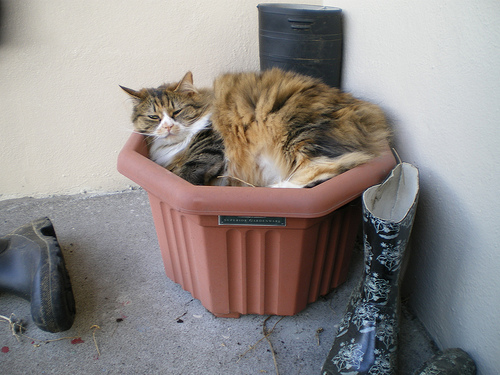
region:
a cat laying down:
[116, 66, 397, 191]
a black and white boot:
[319, 164, 486, 373]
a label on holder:
[214, 217, 292, 230]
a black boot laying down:
[1, 212, 81, 334]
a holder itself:
[117, 134, 399, 319]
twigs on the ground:
[2, 300, 338, 374]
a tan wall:
[4, 0, 498, 369]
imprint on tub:
[148, 207, 357, 322]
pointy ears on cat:
[115, 69, 200, 97]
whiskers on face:
[128, 117, 210, 137]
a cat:
[121, 87, 236, 152]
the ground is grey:
[139, 319, 186, 361]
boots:
[331, 298, 397, 372]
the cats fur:
[228, 77, 313, 129]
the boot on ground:
[3, 224, 83, 331]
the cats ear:
[171, 76, 198, 91]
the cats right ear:
[116, 82, 144, 102]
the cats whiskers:
[125, 127, 148, 138]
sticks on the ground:
[248, 325, 286, 365]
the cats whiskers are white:
[183, 123, 205, 132]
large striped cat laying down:
[119, 69, 362, 171]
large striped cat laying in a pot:
[137, 78, 382, 258]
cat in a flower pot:
[134, 74, 354, 308]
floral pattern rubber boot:
[343, 175, 392, 374]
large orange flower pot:
[123, 140, 371, 299]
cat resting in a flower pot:
[118, 44, 374, 234]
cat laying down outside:
[127, 59, 347, 255]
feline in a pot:
[124, 75, 379, 260]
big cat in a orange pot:
[112, 54, 366, 230]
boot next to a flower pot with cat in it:
[358, 180, 403, 372]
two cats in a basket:
[98, 63, 418, 323]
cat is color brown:
[208, 65, 393, 191]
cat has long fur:
[209, 65, 401, 192]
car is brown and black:
[111, 62, 226, 187]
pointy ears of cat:
[110, 65, 197, 98]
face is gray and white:
[139, 84, 202, 139]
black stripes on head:
[139, 85, 184, 112]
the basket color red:
[110, 152, 391, 322]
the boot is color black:
[5, 212, 80, 333]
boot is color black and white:
[309, 159, 431, 374]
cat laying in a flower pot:
[97, 46, 397, 351]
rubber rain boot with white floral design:
[329, 150, 439, 372]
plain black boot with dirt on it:
[6, 196, 90, 351]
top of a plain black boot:
[231, 0, 366, 76]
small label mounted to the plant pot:
[211, 211, 296, 223]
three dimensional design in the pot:
[212, 226, 302, 326]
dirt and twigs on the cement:
[159, 312, 294, 371]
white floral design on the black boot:
[353, 297, 389, 334]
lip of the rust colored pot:
[177, 183, 321, 231]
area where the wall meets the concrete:
[27, 186, 89, 218]